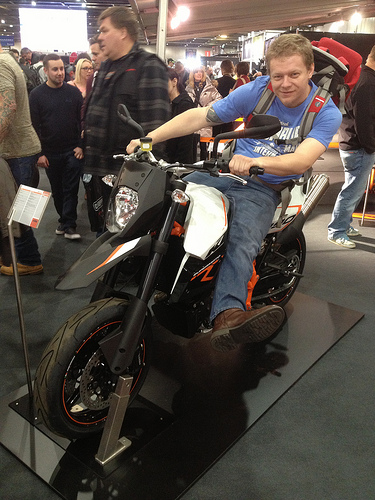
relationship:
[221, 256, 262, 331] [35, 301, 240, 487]
leg of a man ridding a motor bike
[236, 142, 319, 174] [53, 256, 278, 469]
hand of a man ridding a motor bike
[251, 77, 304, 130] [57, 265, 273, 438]
head of a man ridding a motor bike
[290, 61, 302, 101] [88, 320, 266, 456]
eye of a man ridding a motor bike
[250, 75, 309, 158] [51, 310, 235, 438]
mouth of a man ridding a motor bike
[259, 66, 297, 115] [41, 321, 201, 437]
nose of a man ridding a motor bike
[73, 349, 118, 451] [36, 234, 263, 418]
wheel of motor bike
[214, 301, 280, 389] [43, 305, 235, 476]
shoe of a man riding a motor bike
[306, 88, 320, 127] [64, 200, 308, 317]
ear of a man riding a motor bike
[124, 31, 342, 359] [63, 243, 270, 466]
boy on a motor bike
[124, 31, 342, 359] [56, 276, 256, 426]
boy sitting on motorcycle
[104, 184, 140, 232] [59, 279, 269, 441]
headlight of motorcycle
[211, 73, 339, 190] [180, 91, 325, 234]
shirt man wearing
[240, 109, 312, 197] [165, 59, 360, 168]
shirt man wearing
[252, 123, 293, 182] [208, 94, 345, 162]
print on shirt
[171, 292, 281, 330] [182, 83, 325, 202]
left shoe worn by man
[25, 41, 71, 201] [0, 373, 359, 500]
man walking around floor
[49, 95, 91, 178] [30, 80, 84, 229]
outfit man outfit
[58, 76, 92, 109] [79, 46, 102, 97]
eyeglasses woman wearing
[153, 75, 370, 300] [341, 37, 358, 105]
boy with a red backpack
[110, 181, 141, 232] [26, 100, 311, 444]
headlight on motorcycle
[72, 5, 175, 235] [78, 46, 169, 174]
man wearing shirt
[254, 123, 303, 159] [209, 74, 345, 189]
print on shirt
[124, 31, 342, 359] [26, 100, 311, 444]
boy on motorcycle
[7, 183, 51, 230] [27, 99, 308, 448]
sign in front of bike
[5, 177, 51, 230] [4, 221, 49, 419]
sign on pole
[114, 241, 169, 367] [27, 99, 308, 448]
frame on bike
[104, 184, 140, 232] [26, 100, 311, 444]
headlight on motorcycle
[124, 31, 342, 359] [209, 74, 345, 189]
boy wearing shirt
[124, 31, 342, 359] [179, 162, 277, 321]
boy wearing jeans